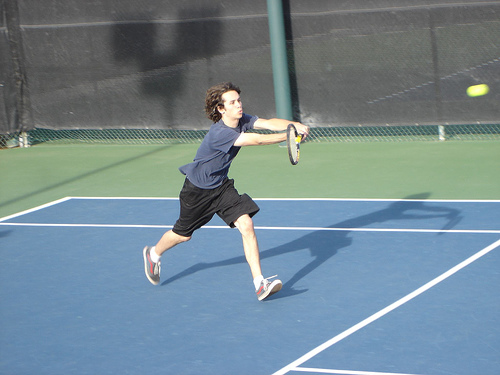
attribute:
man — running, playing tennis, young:
[140, 79, 310, 303]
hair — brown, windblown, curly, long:
[205, 82, 241, 121]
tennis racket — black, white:
[288, 122, 311, 166]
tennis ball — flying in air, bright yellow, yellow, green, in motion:
[467, 82, 488, 98]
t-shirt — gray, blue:
[179, 114, 257, 191]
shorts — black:
[172, 176, 258, 241]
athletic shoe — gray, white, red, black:
[139, 244, 162, 283]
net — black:
[1, 2, 499, 141]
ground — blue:
[1, 195, 498, 374]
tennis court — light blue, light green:
[1, 132, 499, 373]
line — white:
[2, 218, 499, 238]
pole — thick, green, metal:
[269, 1, 296, 147]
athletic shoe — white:
[253, 278, 282, 301]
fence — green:
[2, 2, 499, 139]